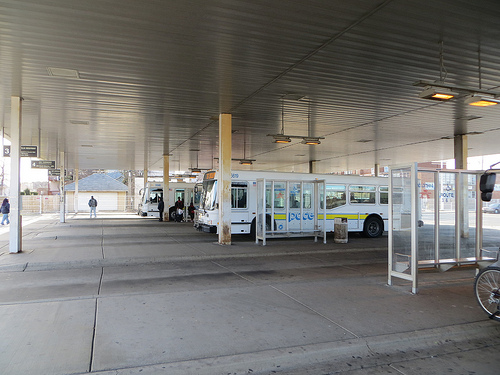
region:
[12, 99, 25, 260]
a white metal pole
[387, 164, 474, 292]
a glass wall panel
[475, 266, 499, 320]
a bikecycle wheel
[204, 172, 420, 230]
a white bus with windows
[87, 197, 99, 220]
a man in a building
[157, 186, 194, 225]
a group of people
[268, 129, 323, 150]
lights on a ceil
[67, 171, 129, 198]
a gray tile roof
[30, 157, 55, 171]
a brown and white sign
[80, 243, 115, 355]
a crack in the concrete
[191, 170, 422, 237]
The bus is white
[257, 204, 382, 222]
Yellow stripe down side of bus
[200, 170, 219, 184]
Orange sign on front of bus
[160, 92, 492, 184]
Square yellow lights hanging from ceiling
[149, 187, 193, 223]
People standing next to the bus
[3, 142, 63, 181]
Black signs hanging from ceiling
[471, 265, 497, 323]
Black and silver tire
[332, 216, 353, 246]
The trash can is tan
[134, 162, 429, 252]
The buses are stopped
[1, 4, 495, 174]
The ceiling is silver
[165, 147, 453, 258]
a white bus is parked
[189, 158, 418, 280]
the bus is white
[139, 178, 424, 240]
buses parked at a bus station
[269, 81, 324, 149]
two lights hanging from a ceiling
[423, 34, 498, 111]
two lights hanging from a ceiling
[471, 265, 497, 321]
a bicycle tire on the ground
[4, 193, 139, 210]
a fence behind a person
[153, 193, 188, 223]
people standing next to a bus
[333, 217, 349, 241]
a trash can next to the bus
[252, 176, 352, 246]
a bus seat next to a trash can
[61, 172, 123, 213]
a building behind the fence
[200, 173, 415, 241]
a bus next to a trash can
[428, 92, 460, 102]
ceiling light is on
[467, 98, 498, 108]
ceiling light is on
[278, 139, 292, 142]
ceiling light is on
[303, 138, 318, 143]
ceiling light is on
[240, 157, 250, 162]
ceiling light is on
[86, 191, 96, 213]
man wearing white pants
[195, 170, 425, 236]
bus is white with yellow stripe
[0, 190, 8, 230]
man wearing black jacket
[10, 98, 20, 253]
white pillar in building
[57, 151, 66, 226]
white pillar in building